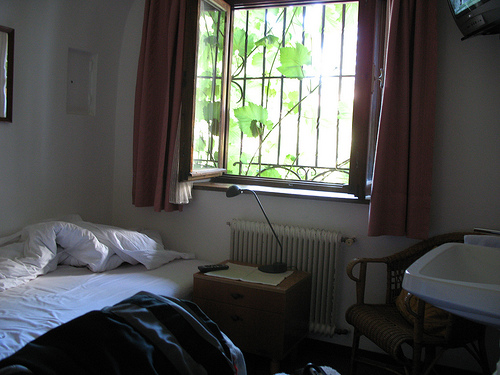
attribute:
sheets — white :
[11, 275, 193, 355]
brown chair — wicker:
[340, 223, 498, 373]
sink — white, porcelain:
[405, 231, 499, 333]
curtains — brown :
[126, 2, 202, 215]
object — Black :
[232, 52, 246, 102]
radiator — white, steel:
[225, 214, 352, 332]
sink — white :
[400, 248, 497, 340]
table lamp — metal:
[227, 193, 288, 275]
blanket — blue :
[8, 287, 252, 373]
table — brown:
[193, 249, 323, 361]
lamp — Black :
[203, 168, 297, 288]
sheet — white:
[9, 219, 194, 363]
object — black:
[230, 179, 294, 276]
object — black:
[233, 172, 302, 281]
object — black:
[244, 188, 298, 283]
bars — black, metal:
[215, 0, 365, 204]